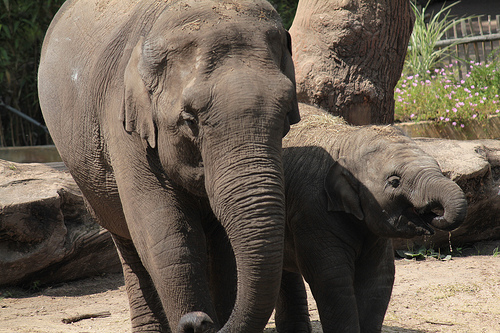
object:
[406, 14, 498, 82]
fence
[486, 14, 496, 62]
post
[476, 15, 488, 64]
post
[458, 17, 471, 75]
post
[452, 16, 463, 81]
post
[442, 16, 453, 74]
post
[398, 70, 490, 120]
wildflowers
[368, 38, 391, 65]
bark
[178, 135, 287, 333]
trunk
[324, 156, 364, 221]
ear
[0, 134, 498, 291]
wall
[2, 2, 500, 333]
enclosure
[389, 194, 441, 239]
mouth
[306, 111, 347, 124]
hay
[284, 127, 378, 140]
back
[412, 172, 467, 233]
trunk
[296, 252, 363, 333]
leg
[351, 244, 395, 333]
leg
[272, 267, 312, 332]
leg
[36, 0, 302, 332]
elephant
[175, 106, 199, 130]
eye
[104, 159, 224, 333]
leg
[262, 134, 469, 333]
baby elephant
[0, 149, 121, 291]
rock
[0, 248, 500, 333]
ground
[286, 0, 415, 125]
tree trunk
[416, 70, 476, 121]
flowers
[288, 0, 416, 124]
tree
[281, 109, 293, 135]
eye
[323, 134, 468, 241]
head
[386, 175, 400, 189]
eye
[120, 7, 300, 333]
head